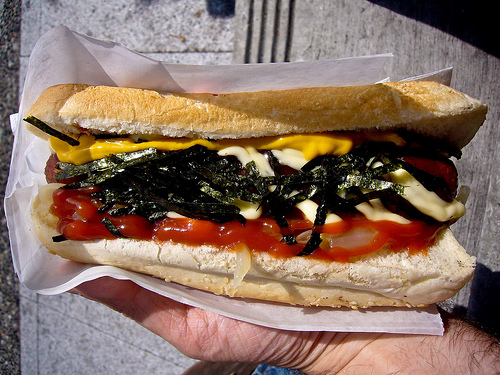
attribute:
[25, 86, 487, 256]
sandwich — full, large, filled, not small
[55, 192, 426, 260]
ketchup — alot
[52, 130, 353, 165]
mustard — bright yellow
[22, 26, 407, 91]
tissue — on top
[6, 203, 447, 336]
tissue — on bottom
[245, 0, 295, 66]
lines — three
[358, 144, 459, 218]
hot dog — on bun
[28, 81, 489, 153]
bun — brown, long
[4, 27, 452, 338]
wrapper — white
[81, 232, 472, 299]
bread — white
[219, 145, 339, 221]
cheese — melted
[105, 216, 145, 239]
peppers — red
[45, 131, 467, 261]
filling — fresh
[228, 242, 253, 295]
onions — chunked, falling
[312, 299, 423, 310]
sesame seeds — at bottom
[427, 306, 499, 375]
hair — alot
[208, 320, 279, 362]
wrinkles — little, alot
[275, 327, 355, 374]
wrinkles — big